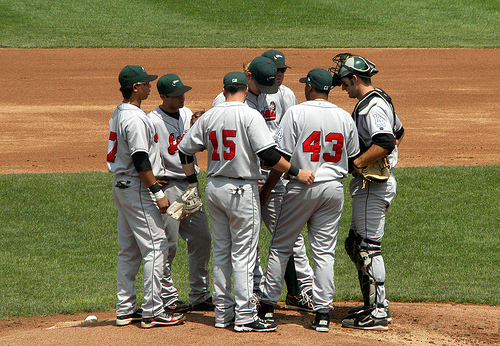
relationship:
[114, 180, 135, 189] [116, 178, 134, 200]
glove in a pocket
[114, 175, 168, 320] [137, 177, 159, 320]
pants have line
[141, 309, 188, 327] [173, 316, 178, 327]
sneaker has trim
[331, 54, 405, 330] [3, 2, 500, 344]
player on field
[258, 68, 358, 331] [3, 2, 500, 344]
player on field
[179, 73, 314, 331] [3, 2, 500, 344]
player on field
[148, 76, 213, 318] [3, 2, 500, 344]
player on field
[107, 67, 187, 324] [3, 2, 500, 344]
player on field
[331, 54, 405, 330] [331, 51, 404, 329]
man in uniform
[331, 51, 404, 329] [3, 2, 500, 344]
uniform for baseball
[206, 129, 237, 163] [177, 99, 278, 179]
number on shirt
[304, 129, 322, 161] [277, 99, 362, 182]
four on shirt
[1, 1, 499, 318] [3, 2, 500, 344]
grass on field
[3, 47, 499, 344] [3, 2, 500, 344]
dirt on field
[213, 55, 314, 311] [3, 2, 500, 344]
man on field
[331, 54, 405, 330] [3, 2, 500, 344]
man on field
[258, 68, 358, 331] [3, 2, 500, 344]
man on field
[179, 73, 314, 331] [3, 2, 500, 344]
man on field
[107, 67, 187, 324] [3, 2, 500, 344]
man on field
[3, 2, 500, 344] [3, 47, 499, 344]
field with dirt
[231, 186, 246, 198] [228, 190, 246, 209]
glove in pocket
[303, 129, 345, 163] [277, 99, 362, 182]
number on jersey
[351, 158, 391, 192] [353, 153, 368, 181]
player's left hand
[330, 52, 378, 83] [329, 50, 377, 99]
helmet on head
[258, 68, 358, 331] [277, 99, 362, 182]
guy in jersey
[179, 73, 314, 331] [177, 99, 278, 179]
guy in jersey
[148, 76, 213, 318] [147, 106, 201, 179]
guy in jersey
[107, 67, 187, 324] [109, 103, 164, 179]
guy in jersey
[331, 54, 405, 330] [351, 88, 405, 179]
guy in jersey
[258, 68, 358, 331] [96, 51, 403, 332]
player of team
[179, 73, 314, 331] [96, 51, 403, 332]
player of team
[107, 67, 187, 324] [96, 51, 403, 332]
player of team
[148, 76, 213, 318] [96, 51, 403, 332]
player of team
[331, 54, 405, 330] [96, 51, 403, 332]
player of team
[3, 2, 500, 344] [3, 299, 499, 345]
baseball pitchers mound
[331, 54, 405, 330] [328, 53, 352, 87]
catcher wearing mask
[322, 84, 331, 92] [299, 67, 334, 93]
white on cap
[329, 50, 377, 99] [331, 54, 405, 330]
head of man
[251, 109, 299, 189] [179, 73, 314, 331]
arm of man